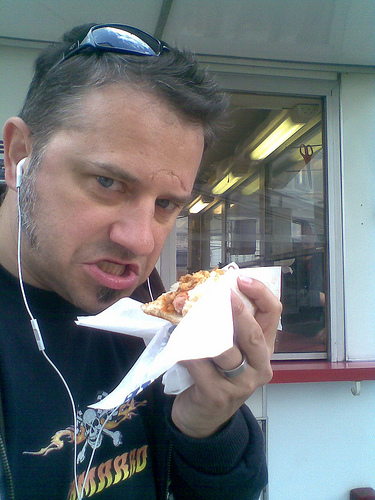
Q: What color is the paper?
A: White.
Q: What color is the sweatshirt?
A: Black.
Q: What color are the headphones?
A: White.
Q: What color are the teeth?
A: Yellow.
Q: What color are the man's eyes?
A: Blue.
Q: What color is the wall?
A: White.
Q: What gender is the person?
A: Male.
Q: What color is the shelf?
A: Red.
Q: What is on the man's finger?
A: Ring.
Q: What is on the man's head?
A: Glasses.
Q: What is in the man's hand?
A: Hot Dog.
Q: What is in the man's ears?
A: Headphones.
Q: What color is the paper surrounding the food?
A: White.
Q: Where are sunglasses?
A: On man's head.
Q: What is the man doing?
A: Eating.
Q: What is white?
A: Napkin.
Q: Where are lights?
A: On ceiling.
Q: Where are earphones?
A: In man's ears.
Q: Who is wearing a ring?
A: The man.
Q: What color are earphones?
A: White.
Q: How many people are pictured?
A: One.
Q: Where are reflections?
A: On the window.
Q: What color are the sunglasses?
A: Black.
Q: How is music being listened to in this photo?
A: With earbuds.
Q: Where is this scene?
A: In front of a store.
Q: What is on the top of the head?
A: Glasses.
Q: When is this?
A: Daytime.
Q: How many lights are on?
A: 3.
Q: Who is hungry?
A: The man.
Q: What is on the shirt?
A: Crossbones.